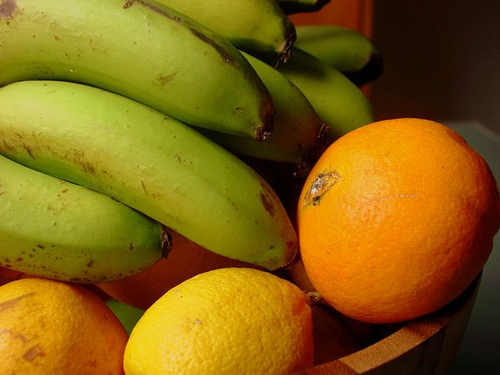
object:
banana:
[0, 0, 278, 143]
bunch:
[0, 1, 385, 284]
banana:
[0, 77, 300, 273]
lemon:
[120, 265, 315, 374]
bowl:
[296, 243, 483, 374]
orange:
[294, 117, 499, 325]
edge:
[399, 263, 486, 352]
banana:
[0, 157, 175, 286]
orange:
[1, 275, 130, 373]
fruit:
[0, 0, 497, 372]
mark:
[0, 290, 36, 315]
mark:
[16, 344, 41, 364]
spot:
[311, 175, 324, 196]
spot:
[311, 193, 322, 207]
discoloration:
[185, 26, 234, 62]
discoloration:
[257, 189, 277, 217]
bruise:
[304, 171, 343, 207]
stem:
[255, 124, 276, 142]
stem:
[297, 287, 310, 301]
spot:
[24, 142, 36, 161]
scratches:
[357, 191, 423, 209]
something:
[281, 0, 373, 105]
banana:
[187, 47, 327, 172]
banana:
[256, 45, 376, 138]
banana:
[288, 23, 380, 79]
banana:
[146, 0, 297, 61]